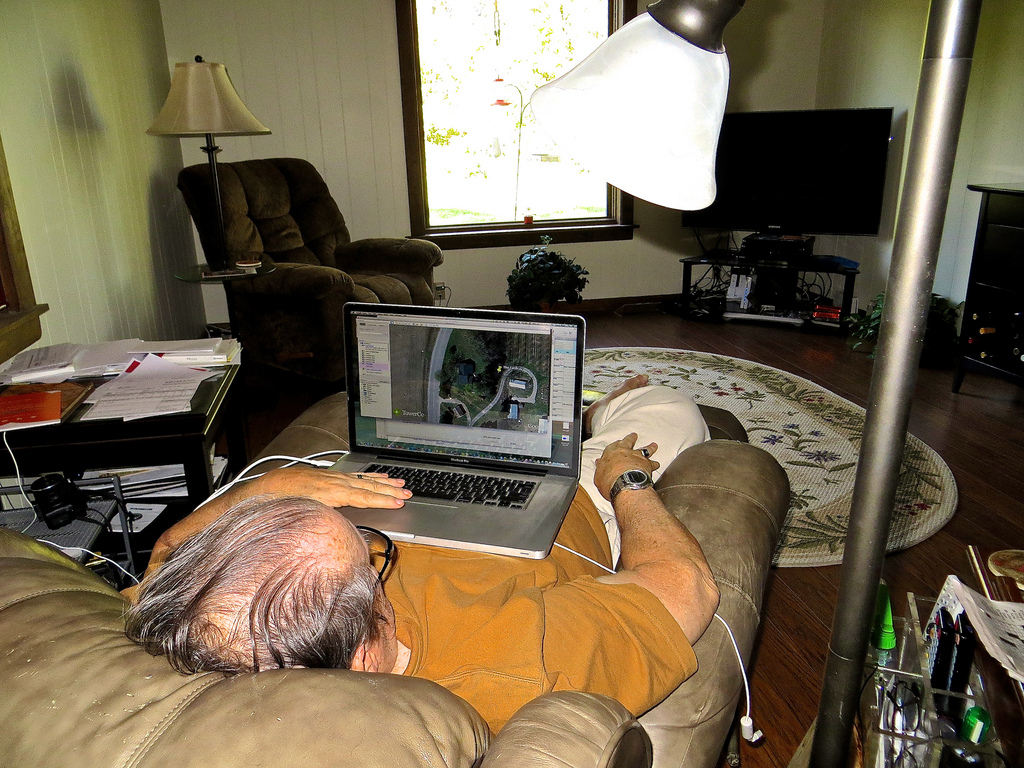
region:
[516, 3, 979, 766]
Silver floor lamp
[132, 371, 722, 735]
Man lounging in recliner chair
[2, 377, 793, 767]
Dark tan recliner chair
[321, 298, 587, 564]
Silver laptop computer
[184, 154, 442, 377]
Brown recliner chair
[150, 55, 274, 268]
Lamp sitting on end table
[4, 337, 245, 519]
Black end table next to chair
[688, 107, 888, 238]
Black flat screen TV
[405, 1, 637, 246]
Window with wooden trim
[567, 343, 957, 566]
Oval floor rug with floral pattern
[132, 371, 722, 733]
Man sitting in recliner chair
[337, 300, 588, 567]
Silver laptop computer with black keyboard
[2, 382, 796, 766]
Tan recliner chair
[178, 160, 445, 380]
Dark brown chair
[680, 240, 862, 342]
Black TV stand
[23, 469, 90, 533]
Black coffee mug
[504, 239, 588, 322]
Plant sitting on floor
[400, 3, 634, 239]
light shining through window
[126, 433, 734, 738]
man sitting on couch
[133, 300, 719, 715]
man using laptop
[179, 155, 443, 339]
rocking chair in corner of room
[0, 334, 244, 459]
end table with lots of papers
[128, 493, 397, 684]
man with a balding head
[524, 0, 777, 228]
lamp hanging above chair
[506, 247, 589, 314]
plant sitting on floor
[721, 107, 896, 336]
tv in corner of room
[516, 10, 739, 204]
white glass tulip shaped light shade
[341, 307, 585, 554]
laptop showing a sattelite image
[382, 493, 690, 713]
man's gold colored t-shirt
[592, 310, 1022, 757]
dark colored hardwood flooring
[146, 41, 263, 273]
candle stick table lamp with ecru shade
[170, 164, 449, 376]
chocolate brown barcalounger by the window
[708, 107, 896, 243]
large black flat screen TV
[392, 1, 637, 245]
window with dark wood frame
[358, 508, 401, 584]
man wears black rimmed eyeglasses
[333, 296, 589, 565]
opened laptop sitting on man's chest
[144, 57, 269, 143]
lampshade covering table lamp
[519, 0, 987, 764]
pole lamp with white fixture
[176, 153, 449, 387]
dark recliner near large window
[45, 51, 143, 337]
shadow of table lamp projected onto wall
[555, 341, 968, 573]
large area rug covering wooden floor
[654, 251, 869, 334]
small corner shelf holding large television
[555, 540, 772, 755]
white ear bud under man's laptop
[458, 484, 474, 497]
A key on a keyboard.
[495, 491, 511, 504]
A key on a keyboard.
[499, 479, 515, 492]
A key on a keyboard.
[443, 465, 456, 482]
A key on a keyboard.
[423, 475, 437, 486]
A key on a keyboard.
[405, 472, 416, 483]
A key on a keyboard.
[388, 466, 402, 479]
A key on a keyboard.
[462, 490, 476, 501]
A key on a keyboard.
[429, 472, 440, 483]
A key on a keyboard.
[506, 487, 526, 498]
A key on a keyboard.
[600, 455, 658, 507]
Watch on a man's wrist.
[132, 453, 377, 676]
Balding head on a man.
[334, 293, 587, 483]
Moniter on a laptop.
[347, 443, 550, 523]
Keyboard on a laptop.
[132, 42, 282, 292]
Lamp by a chair.